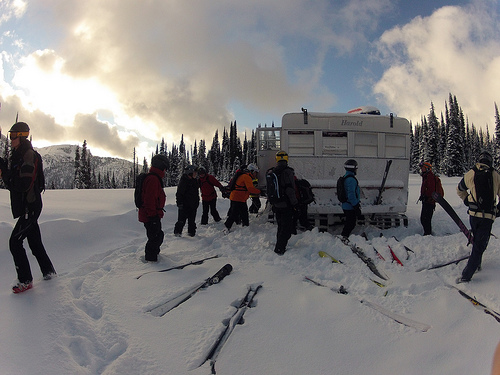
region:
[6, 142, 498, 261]
there are many people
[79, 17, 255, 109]
the sky is cloudy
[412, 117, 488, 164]
there are trees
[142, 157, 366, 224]
the people are in many colors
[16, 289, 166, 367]
there s a lot of snow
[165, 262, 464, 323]
it looks like they were skeeying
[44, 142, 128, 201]
there is a mountian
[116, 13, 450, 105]
it is day time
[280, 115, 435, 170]
there is a white truck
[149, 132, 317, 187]
the people all have helments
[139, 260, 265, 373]
Skis on the ground.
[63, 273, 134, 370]
Boot prints in the snow.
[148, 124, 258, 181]
Pine trees in the background.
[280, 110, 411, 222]
A white camper trailer.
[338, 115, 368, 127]
Harold written across the top of the camper.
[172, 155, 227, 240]
Two people walking in the snow.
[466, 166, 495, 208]
A large black back pack.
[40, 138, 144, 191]
A snowy mountain in the distance.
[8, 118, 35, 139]
A helmet with yellow goggles.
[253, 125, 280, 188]
An open camper door.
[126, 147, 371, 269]
People preparing to snow ski.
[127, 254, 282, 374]
Skis lying on snow covered ground.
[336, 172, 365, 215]
Woman dressed in blue jacket.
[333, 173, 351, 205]
Woman carrying black backpack on back.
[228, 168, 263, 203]
Man dressed in orange jacket.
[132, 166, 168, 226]
Woman dressed in red jacket.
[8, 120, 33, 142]
Person wearing helmet on head.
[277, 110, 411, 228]
Rear end of snow vehicle.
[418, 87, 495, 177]
Snow covered pine trees in background.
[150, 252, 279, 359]
three skis in the snow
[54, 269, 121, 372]
foot tracks in the snow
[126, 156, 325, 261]
people gathered by white truck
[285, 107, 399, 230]
white camper in the snow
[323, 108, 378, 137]
name on the camper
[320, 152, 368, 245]
person with blue jacket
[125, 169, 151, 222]
backpack on the back of person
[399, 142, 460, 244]
person holding the ski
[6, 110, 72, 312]
man walking away from camper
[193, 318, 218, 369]
There are some black skis here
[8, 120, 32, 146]
This person is wearing a hat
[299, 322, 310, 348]
There are bright white snow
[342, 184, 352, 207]
This person has a blue jacket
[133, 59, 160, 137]
There are clouds visible in the sky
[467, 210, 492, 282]
There are jeans visible here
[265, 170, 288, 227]
There is a backpack visible here